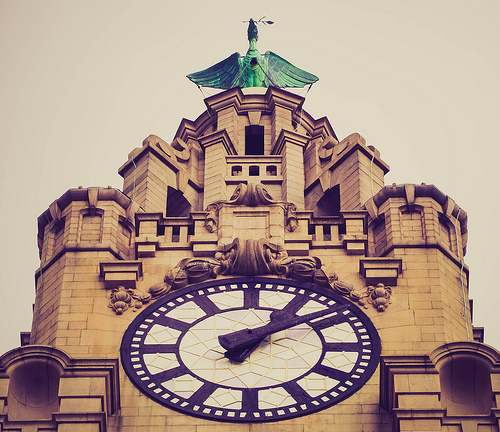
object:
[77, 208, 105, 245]
window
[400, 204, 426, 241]
window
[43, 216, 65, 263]
window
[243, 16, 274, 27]
rose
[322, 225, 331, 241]
window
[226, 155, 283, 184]
railing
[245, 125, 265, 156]
doorway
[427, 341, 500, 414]
arch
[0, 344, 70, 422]
arch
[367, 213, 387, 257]
window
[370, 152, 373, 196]
pipe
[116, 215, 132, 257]
window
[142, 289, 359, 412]
clock face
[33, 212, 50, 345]
pipe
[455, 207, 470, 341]
pipe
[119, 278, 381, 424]
clock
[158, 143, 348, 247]
women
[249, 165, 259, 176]
window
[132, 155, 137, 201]
pipe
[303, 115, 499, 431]
side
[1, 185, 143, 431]
side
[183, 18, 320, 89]
bird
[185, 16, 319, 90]
statue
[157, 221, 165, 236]
window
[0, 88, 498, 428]
building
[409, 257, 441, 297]
stone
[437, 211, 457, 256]
window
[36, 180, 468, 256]
railings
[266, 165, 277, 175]
window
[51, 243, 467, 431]
wall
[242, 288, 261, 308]
stripe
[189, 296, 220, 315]
stripe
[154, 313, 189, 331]
stripe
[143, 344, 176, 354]
stripe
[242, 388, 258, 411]
stripe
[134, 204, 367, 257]
balcony